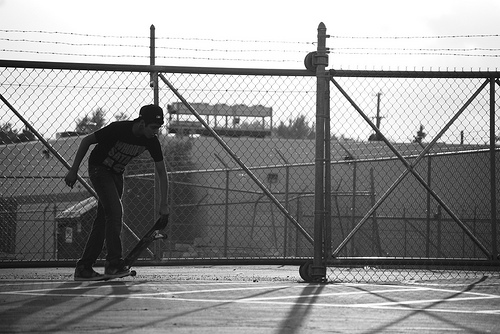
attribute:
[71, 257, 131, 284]
shoes — skate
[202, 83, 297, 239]
fence — chain link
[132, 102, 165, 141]
head — man's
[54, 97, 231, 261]
guy — skateboarding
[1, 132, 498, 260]
building — white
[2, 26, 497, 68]
wire — barbed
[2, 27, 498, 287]
fence — chain link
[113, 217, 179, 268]
skateboard — tipped up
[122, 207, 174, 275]
skateboard — black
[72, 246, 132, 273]
shoes — high tops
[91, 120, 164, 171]
shirt — black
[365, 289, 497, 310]
line — white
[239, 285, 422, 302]
line — white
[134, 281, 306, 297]
line — white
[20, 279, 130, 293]
line — white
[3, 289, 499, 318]
line — white